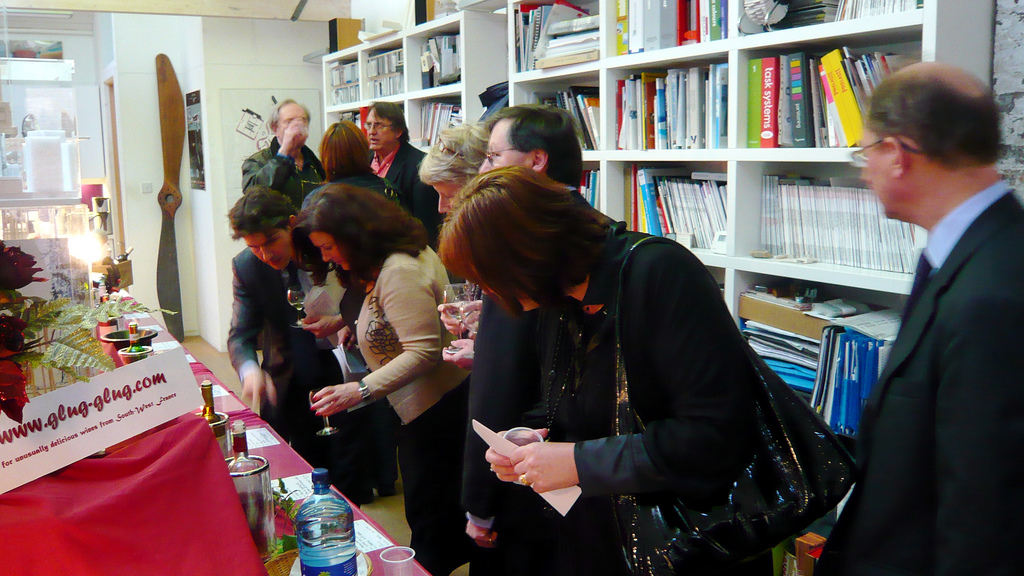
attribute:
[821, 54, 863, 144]
binder — yellow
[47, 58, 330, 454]
sign — white, red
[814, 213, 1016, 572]
suit — dark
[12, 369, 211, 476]
address — website